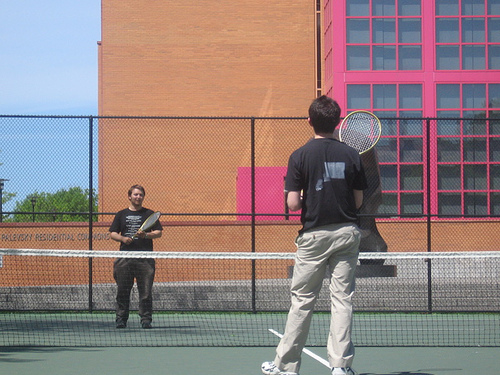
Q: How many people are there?
A: Two.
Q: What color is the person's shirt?
A: Black.